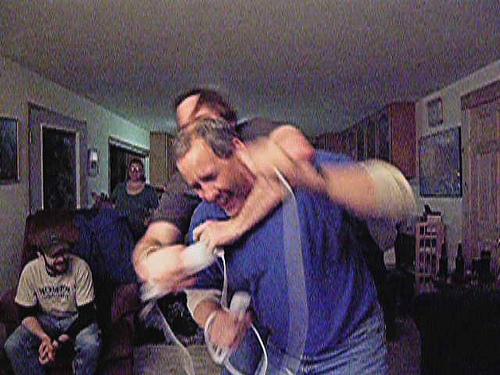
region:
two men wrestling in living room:
[127, 78, 424, 372]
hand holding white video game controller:
[197, 283, 275, 373]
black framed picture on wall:
[403, 121, 467, 203]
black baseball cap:
[33, 225, 78, 262]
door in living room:
[455, 73, 499, 278]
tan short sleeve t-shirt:
[10, 255, 100, 325]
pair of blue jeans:
[3, 311, 105, 372]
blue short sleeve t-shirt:
[180, 146, 385, 356]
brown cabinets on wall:
[312, 95, 422, 182]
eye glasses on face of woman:
[124, 163, 146, 178]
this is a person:
[174, 129, 396, 369]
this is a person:
[4, 223, 121, 373]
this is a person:
[93, 139, 163, 237]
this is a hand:
[234, 133, 417, 225]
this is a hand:
[198, 116, 311, 283]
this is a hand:
[134, 172, 261, 361]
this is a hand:
[57, 270, 101, 368]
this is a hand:
[15, 272, 61, 372]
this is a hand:
[79, 172, 124, 210]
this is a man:
[164, 110, 394, 367]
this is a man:
[124, 63, 321, 306]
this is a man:
[12, 238, 107, 371]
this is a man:
[80, 157, 183, 284]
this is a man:
[81, 208, 174, 344]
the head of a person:
[156, 120, 243, 220]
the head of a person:
[138, 75, 258, 188]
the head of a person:
[31, 229, 78, 289]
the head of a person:
[101, 148, 157, 197]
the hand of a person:
[256, 143, 421, 248]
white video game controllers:
[141, 239, 272, 373]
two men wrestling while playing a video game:
[125, 82, 419, 374]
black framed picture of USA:
[410, 123, 467, 200]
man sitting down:
[4, 220, 108, 373]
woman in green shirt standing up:
[88, 150, 164, 247]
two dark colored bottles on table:
[428, 234, 470, 291]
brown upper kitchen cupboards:
[288, 93, 420, 183]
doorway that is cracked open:
[20, 96, 93, 225]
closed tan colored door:
[452, 71, 498, 293]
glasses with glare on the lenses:
[125, 160, 145, 174]